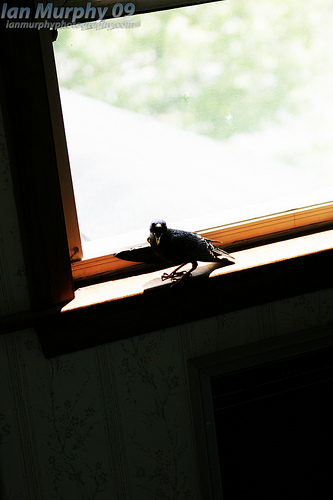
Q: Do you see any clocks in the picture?
A: No, there are no clocks.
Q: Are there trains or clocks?
A: No, there are no clocks or trains.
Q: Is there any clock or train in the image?
A: No, there are no clocks or trains.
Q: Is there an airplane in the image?
A: No, there are no airplanes.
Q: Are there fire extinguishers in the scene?
A: No, there are no fire extinguishers.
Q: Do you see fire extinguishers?
A: No, there are no fire extinguishers.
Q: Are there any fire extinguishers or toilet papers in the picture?
A: No, there are no fire extinguishers or toilet papers.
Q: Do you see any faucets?
A: No, there are no faucets.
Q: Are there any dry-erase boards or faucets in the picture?
A: No, there are no faucets or dry-erase boards.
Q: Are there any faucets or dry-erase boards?
A: No, there are no faucets or dry-erase boards.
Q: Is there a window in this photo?
A: Yes, there is a window.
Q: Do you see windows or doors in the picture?
A: Yes, there is a window.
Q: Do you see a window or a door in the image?
A: Yes, there is a window.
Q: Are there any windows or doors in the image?
A: Yes, there is a window.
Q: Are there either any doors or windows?
A: Yes, there is a window.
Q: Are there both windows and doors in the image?
A: No, there is a window but no doors.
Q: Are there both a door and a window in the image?
A: No, there is a window but no doors.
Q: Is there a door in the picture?
A: No, there are no doors.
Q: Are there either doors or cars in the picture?
A: No, there are no doors or cars.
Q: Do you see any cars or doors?
A: No, there are no doors or cars.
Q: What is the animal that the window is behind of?
A: The animal is a bird.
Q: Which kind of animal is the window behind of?
A: The window is behind the bird.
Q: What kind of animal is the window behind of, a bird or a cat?
A: The window is behind a bird.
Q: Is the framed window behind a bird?
A: Yes, the window is behind a bird.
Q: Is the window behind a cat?
A: No, the window is behind a bird.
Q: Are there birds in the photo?
A: Yes, there is a bird.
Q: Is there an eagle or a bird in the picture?
A: Yes, there is a bird.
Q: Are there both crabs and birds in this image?
A: No, there is a bird but no crabs.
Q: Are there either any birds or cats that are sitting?
A: Yes, the bird is sitting.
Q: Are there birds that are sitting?
A: Yes, there is a bird that is sitting.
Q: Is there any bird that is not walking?
A: Yes, there is a bird that is sitting.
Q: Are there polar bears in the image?
A: No, there are no polar bears.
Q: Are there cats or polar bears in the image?
A: No, there are no polar bears or cats.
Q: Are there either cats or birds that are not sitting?
A: No, there is a bird but it is sitting.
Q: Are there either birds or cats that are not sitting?
A: No, there is a bird but it is sitting.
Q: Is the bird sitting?
A: Yes, the bird is sitting.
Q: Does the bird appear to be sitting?
A: Yes, the bird is sitting.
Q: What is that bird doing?
A: The bird is sitting.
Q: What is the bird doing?
A: The bird is sitting.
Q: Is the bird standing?
A: No, the bird is sitting.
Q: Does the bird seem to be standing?
A: No, the bird is sitting.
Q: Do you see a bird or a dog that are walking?
A: No, there is a bird but it is sitting.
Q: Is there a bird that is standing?
A: No, there is a bird but it is sitting.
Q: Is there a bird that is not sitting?
A: No, there is a bird but it is sitting.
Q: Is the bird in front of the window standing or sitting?
A: The bird is sitting.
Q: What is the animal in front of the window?
A: The animal is a bird.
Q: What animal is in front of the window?
A: The animal is a bird.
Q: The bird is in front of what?
A: The bird is in front of the window.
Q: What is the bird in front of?
A: The bird is in front of the window.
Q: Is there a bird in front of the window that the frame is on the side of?
A: Yes, there is a bird in front of the window.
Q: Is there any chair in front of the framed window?
A: No, there is a bird in front of the window.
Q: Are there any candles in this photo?
A: No, there are no candles.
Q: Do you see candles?
A: No, there are no candles.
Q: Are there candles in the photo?
A: No, there are no candles.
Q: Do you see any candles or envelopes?
A: No, there are no candles or envelopes.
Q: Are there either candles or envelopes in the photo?
A: No, there are no candles or envelopes.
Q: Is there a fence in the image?
A: No, there are no fences.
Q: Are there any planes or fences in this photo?
A: No, there are no fences or planes.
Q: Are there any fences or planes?
A: No, there are no fences or planes.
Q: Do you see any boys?
A: No, there are no boys.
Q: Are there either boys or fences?
A: No, there are no boys or fences.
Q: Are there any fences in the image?
A: No, there are no fences.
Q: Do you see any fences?
A: No, there are no fences.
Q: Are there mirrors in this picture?
A: No, there are no mirrors.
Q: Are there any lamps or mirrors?
A: No, there are no mirrors or lamps.